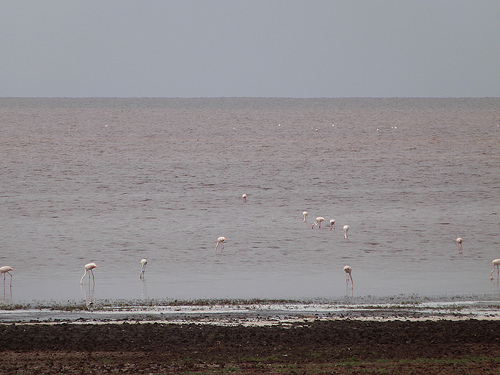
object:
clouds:
[0, 0, 500, 91]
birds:
[139, 258, 147, 279]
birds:
[343, 225, 350, 239]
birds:
[242, 194, 247, 203]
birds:
[302, 211, 308, 223]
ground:
[0, 303, 500, 374]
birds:
[343, 265, 354, 283]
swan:
[0, 265, 14, 287]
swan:
[80, 262, 98, 288]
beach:
[0, 297, 499, 375]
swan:
[490, 259, 500, 282]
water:
[3, 99, 498, 191]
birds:
[330, 219, 336, 232]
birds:
[215, 237, 226, 254]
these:
[69, 194, 177, 292]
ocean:
[0, 96, 500, 302]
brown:
[0, 97, 499, 192]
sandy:
[179, 323, 375, 363]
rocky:
[389, 294, 499, 358]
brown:
[0, 320, 498, 353]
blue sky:
[0, 0, 500, 95]